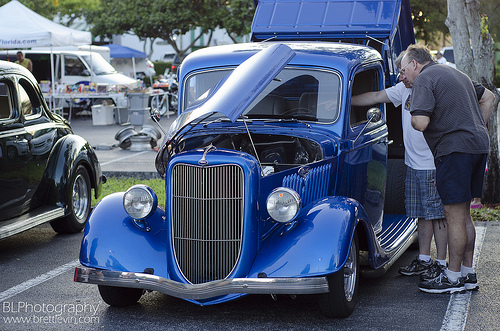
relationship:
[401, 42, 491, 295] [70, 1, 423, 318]
man viewing truck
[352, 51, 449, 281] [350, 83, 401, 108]
guy pointing arm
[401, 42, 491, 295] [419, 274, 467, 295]
man with shoe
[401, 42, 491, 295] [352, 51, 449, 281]
man with guy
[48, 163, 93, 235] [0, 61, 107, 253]
tire on car